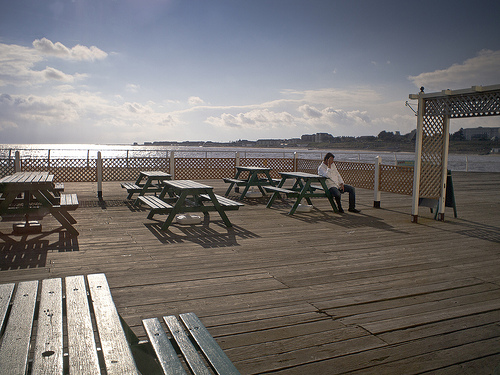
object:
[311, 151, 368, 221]
person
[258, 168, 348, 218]
picnic table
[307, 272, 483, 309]
plank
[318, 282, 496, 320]
plank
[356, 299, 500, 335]
plank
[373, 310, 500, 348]
plank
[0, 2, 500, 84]
sky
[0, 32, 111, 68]
cloud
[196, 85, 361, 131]
cloud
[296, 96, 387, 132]
cloud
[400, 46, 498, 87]
cloud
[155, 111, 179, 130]
cloud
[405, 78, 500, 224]
trellis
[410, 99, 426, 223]
support pole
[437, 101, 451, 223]
support pole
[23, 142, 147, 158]
reflection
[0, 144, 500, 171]
water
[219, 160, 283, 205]
picnic table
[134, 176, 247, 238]
picnic table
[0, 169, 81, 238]
picnic table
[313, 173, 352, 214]
bench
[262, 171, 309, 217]
bench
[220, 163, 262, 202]
bench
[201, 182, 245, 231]
bench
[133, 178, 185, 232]
bench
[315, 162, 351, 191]
shirt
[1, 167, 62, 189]
deck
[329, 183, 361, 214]
blue jeans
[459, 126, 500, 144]
building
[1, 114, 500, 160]
distance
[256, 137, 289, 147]
building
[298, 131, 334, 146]
building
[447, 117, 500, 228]
entrance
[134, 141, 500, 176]
land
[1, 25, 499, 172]
background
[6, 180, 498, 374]
flooring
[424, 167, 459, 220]
sign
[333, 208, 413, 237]
shadow